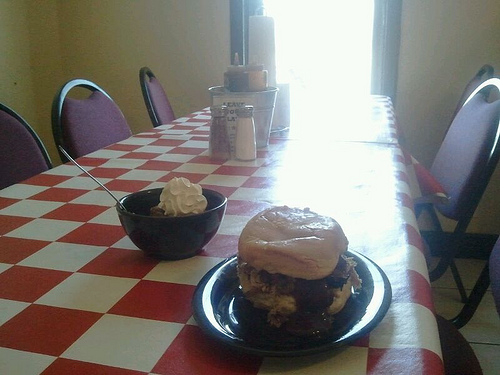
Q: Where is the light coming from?
A: The window.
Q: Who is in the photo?
A: No one.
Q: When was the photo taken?
A: Daytime.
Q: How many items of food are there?
A: Two.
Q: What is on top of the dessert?
A: Whipped cream.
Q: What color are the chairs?
A: Purple and black.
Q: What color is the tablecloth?
A: Red and white.